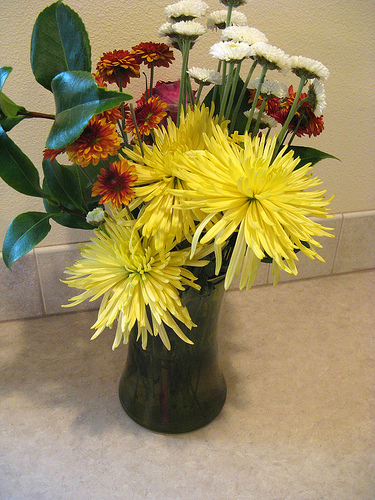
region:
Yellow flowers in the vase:
[62, 102, 333, 349]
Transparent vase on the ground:
[114, 228, 225, 427]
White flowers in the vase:
[153, 0, 324, 116]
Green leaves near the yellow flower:
[1, 0, 132, 270]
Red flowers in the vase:
[43, 42, 179, 208]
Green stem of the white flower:
[177, 40, 189, 113]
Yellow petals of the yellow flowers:
[242, 204, 274, 231]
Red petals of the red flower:
[99, 186, 138, 209]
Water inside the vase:
[118, 343, 226, 433]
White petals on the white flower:
[213, 49, 231, 59]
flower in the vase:
[283, 54, 330, 80]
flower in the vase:
[185, 144, 292, 257]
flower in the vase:
[133, 100, 171, 133]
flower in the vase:
[100, 172, 137, 199]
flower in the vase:
[101, 58, 137, 99]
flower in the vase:
[190, 63, 216, 87]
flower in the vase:
[165, 17, 196, 48]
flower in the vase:
[207, 5, 242, 25]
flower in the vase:
[156, 78, 189, 106]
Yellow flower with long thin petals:
[60, 214, 208, 346]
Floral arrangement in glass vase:
[2, 8, 333, 349]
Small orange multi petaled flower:
[88, 159, 138, 207]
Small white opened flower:
[209, 41, 254, 65]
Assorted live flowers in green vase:
[0, 1, 329, 432]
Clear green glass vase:
[115, 259, 232, 436]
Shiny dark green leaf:
[26, 0, 89, 94]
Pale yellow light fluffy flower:
[171, 124, 335, 289]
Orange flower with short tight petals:
[90, 156, 138, 209]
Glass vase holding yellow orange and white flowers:
[1, 0, 341, 436]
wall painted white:
[325, 2, 373, 142]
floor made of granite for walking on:
[245, 309, 337, 485]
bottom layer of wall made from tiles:
[343, 218, 364, 272]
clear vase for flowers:
[119, 346, 226, 432]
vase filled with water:
[122, 358, 223, 425]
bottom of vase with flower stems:
[128, 360, 204, 418]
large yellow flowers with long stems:
[140, 148, 311, 266]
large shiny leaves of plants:
[0, 150, 86, 228]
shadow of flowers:
[1, 353, 118, 438]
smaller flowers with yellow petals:
[167, 0, 317, 94]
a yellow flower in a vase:
[193, 122, 334, 274]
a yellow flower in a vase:
[128, 136, 213, 238]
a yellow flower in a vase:
[67, 223, 198, 338]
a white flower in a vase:
[307, 78, 328, 118]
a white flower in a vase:
[290, 53, 331, 81]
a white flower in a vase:
[209, 40, 252, 64]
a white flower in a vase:
[172, 18, 208, 41]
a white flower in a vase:
[163, 1, 213, 16]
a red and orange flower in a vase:
[129, 40, 174, 71]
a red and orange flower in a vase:
[89, 164, 139, 206]